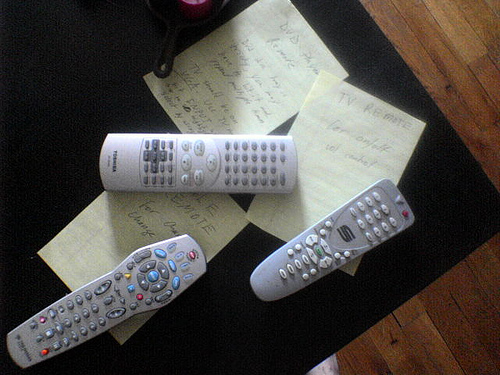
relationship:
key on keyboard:
[371, 190, 380, 202] [348, 187, 402, 243]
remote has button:
[5, 232, 207, 370] [136, 293, 143, 299]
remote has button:
[5, 232, 207, 370] [122, 272, 132, 281]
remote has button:
[5, 232, 207, 370] [92, 280, 112, 295]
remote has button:
[5, 232, 207, 370] [77, 309, 89, 318]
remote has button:
[5, 232, 207, 370] [97, 311, 105, 331]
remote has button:
[5, 232, 207, 370] [63, 318, 71, 328]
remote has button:
[97, 129, 297, 193] [207, 153, 218, 173]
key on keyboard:
[359, 192, 380, 209] [350, 188, 405, 245]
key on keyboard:
[388, 216, 396, 228] [248, 174, 422, 308]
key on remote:
[385, 210, 403, 232] [248, 178, 417, 303]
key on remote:
[321, 216, 331, 231] [248, 178, 417, 303]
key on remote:
[275, 261, 289, 282] [248, 178, 417, 303]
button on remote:
[145, 269, 160, 285] [5, 232, 207, 370]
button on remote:
[124, 282, 137, 299] [5, 232, 207, 370]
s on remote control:
[333, 220, 356, 245] [222, 178, 442, 306]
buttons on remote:
[270, 187, 402, 288] [268, 181, 413, 301]